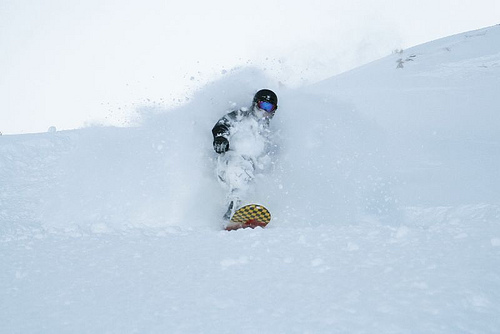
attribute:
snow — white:
[359, 250, 411, 279]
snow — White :
[23, 165, 495, 315]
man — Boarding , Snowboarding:
[211, 89, 278, 221]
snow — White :
[57, 189, 237, 316]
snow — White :
[356, 77, 427, 154]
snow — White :
[157, 58, 269, 120]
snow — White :
[351, 177, 481, 303]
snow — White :
[35, 179, 150, 254]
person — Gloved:
[178, 80, 345, 252]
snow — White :
[0, 23, 497, 332]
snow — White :
[2, 105, 492, 330]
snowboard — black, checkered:
[224, 201, 269, 228]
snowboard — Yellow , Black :
[223, 201, 273, 233]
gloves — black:
[206, 131, 243, 167]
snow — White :
[19, 172, 203, 330]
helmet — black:
[249, 87, 281, 112]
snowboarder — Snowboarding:
[211, 84, 281, 219]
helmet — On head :
[247, 90, 286, 115]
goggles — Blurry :
[254, 95, 276, 110]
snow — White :
[321, 96, 497, 332]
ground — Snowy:
[27, 97, 488, 326]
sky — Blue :
[1, 2, 497, 132]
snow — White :
[302, 142, 436, 211]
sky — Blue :
[4, 5, 209, 111]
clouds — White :
[79, 27, 233, 91]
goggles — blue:
[250, 94, 291, 114]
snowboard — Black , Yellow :
[162, 179, 274, 241]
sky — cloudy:
[9, 11, 246, 71]